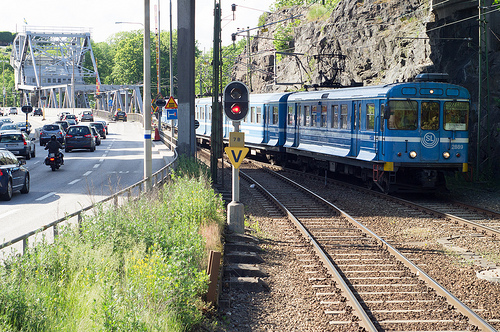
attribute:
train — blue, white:
[154, 87, 468, 192]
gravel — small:
[207, 138, 493, 331]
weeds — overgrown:
[3, 164, 227, 331]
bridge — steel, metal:
[7, 27, 152, 116]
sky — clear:
[0, 1, 264, 58]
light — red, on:
[230, 103, 243, 116]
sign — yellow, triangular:
[221, 144, 251, 170]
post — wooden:
[203, 247, 230, 312]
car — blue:
[1, 151, 29, 195]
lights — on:
[407, 86, 452, 160]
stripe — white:
[249, 124, 467, 149]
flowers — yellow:
[42, 243, 209, 331]